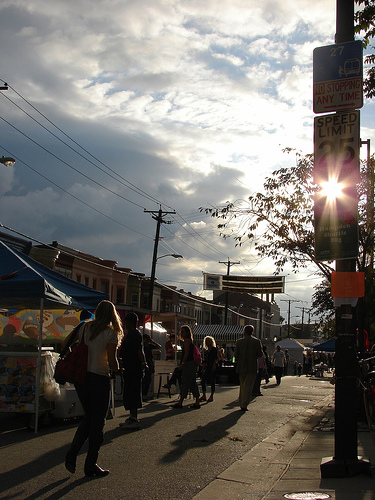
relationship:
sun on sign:
[299, 163, 355, 230] [307, 135, 370, 260]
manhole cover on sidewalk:
[263, 476, 347, 499] [249, 437, 312, 495]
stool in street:
[156, 362, 177, 403] [158, 401, 196, 456]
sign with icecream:
[30, 300, 77, 346] [45, 320, 63, 336]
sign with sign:
[307, 135, 370, 260] [312, 110, 361, 185]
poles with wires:
[142, 190, 176, 298] [38, 110, 131, 205]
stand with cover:
[208, 319, 244, 400] [197, 329, 254, 336]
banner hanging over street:
[205, 264, 286, 296] [158, 401, 196, 456]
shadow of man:
[169, 406, 251, 470] [246, 321, 263, 398]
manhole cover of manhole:
[280, 490, 329, 500] [308, 477, 325, 500]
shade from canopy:
[6, 399, 27, 439] [17, 262, 38, 300]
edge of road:
[167, 401, 295, 486] [104, 421, 179, 491]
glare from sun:
[287, 149, 365, 232] [299, 163, 355, 230]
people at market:
[97, 327, 279, 365] [19, 282, 236, 319]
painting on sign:
[10, 311, 79, 351] [30, 300, 77, 346]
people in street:
[97, 327, 279, 365] [158, 401, 196, 456]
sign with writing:
[321, 270, 370, 297] [342, 271, 362, 281]